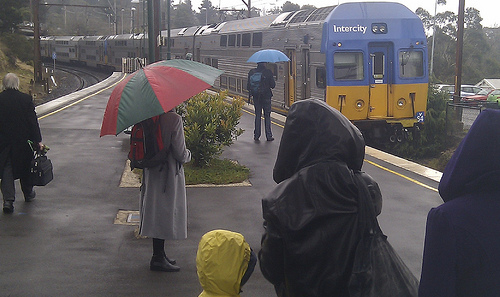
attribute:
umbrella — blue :
[247, 47, 289, 64]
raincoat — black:
[257, 96, 383, 295]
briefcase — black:
[30, 149, 55, 186]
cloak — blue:
[417, 105, 499, 295]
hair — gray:
[1, 68, 21, 88]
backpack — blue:
[243, 69, 269, 101]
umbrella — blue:
[247, 48, 292, 68]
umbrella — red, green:
[126, 113, 188, 271]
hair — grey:
[3, 64, 45, 123]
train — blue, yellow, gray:
[309, 5, 446, 122]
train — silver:
[28, 0, 436, 150]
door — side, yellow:
[288, 55, 300, 105]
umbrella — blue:
[245, 47, 295, 74]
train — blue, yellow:
[298, 0, 483, 168]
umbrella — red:
[98, 58, 223, 135]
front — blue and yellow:
[301, 4, 437, 149]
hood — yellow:
[182, 227, 262, 294]